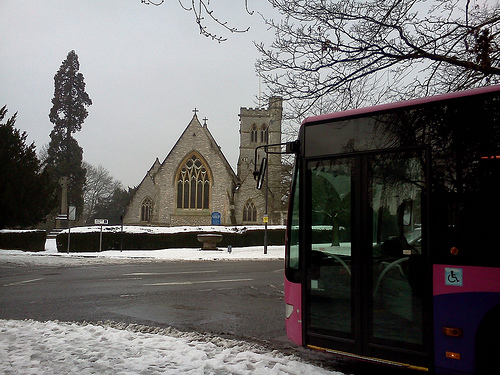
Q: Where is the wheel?
A: On the bus.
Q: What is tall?
A: A tree.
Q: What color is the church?
A: Light brown.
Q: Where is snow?
A: On the ground.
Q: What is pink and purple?
A: A bus.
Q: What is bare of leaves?
A: Tree on right.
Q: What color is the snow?
A: White.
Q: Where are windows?
A: On bus.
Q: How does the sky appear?
A: Overcast.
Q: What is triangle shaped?
A: The church.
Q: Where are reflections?
A: On the bus.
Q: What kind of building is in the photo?
A: Church.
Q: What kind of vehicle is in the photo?
A: Bus.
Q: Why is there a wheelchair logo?
A: Accessible bus.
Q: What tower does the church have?
A: Belltower.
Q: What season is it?
A: Winter.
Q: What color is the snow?
A: White.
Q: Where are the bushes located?
A: In front of the church.